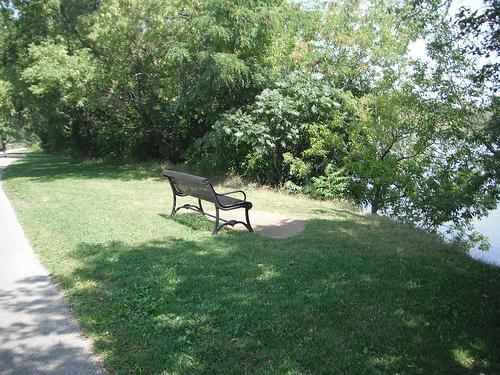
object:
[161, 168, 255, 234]
chair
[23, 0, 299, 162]
trees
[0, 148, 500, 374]
grass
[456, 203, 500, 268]
water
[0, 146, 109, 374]
sidewalk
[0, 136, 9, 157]
person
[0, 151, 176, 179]
shadow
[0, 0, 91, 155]
tree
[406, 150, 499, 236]
tree